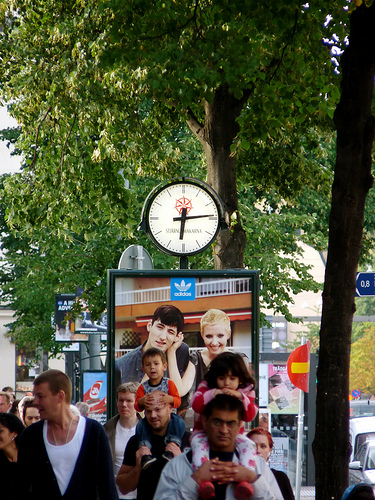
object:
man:
[15, 369, 119, 499]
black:
[16, 416, 119, 500]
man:
[115, 389, 188, 499]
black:
[123, 434, 187, 500]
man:
[149, 392, 286, 499]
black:
[185, 447, 236, 499]